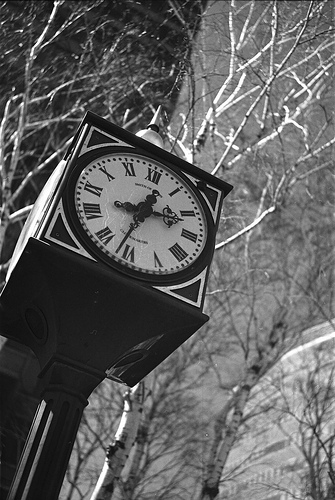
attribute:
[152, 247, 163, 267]
number — roman, five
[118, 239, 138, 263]
roman number — six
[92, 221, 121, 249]
roman number — seven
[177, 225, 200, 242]
numeral — black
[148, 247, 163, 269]
numeral — black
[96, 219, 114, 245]
numeral — black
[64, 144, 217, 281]
clock — round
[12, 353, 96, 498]
pole — metal, black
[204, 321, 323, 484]
building — large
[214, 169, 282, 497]
tree — thin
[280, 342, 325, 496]
tree — thin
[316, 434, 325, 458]
tree — thin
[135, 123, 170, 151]
globe — round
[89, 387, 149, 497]
tree — thin, white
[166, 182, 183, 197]
number — roman, one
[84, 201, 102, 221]
number — roman, eight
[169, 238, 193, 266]
number — roman, clock, four